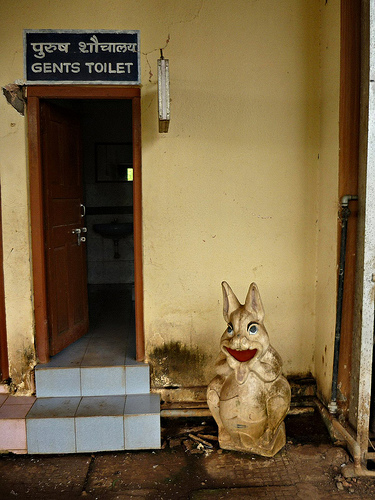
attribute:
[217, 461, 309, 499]
floor — tile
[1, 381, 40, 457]
step — pink, brick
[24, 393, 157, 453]
step — blue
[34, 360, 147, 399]
step — blue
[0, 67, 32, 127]
wall — crumbling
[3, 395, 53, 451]
step — pink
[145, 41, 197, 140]
light — small, cylindrical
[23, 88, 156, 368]
doorway — open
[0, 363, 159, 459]
tiles — blue, pink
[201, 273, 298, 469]
statue — ceramic, grinning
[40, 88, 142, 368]
restroom — public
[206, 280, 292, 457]
rabbit — white, brown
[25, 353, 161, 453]
steps — blue